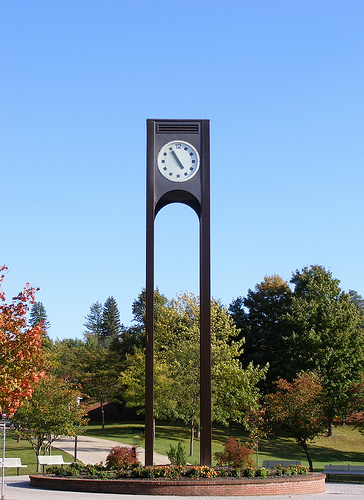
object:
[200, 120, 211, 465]
pole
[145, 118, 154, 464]
pole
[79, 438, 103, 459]
ground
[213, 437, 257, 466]
red bush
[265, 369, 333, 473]
tree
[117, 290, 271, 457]
tree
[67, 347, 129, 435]
tree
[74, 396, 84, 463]
light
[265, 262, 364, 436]
tree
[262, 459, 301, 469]
bench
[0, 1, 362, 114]
man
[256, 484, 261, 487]
brick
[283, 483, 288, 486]
brick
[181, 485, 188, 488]
brick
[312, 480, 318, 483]
brick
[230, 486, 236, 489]
brick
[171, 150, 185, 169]
clock hand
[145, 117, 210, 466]
clock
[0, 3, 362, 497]
park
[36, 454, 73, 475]
bench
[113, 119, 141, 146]
sky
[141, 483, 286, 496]
wall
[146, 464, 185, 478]
flowers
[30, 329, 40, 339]
leaves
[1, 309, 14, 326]
leaves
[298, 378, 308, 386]
leaves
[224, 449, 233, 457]
leaves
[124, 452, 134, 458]
leaves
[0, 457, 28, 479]
bench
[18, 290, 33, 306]
leaves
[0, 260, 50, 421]
tree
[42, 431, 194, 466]
pathway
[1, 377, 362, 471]
hill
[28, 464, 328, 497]
bed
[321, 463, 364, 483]
bench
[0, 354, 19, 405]
leaves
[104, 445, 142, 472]
bush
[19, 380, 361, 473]
background